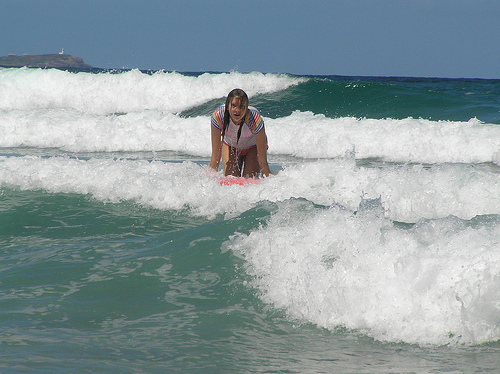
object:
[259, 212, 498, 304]
white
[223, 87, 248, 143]
hair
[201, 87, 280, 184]
woman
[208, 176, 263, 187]
pink board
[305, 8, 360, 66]
white clouds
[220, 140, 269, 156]
red trunks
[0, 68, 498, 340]
waves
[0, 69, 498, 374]
water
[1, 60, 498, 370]
sea water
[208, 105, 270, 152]
shirt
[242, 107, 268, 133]
shoulders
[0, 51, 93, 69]
land mass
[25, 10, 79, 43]
white clouds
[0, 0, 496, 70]
blue sky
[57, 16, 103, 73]
white clouds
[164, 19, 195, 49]
white clouds